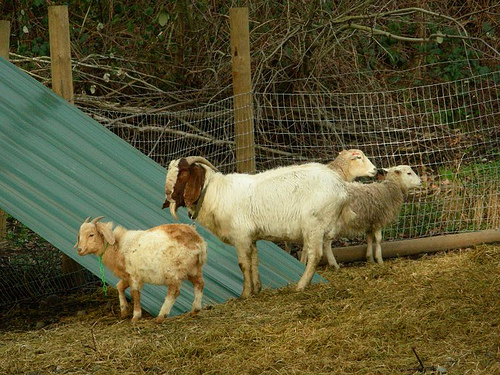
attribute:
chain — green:
[96, 254, 111, 294]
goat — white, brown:
[162, 152, 356, 297]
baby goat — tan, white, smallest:
[73, 217, 208, 322]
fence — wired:
[6, 73, 500, 309]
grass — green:
[3, 255, 498, 373]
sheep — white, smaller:
[286, 150, 428, 270]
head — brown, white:
[161, 152, 220, 214]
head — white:
[74, 216, 117, 257]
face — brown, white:
[164, 159, 184, 201]